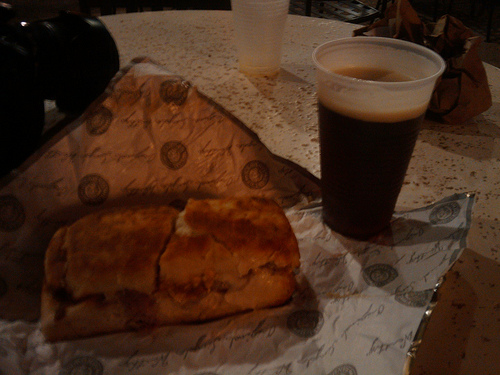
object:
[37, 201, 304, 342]
sandwich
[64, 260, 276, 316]
meat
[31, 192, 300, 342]
bread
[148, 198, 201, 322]
cut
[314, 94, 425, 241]
ale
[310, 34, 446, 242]
cup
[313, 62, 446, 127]
head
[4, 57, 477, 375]
paper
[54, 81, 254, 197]
design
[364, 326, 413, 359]
words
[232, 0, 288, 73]
cup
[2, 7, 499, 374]
table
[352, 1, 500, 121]
bag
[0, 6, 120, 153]
camera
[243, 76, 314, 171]
crumbs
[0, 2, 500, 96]
background